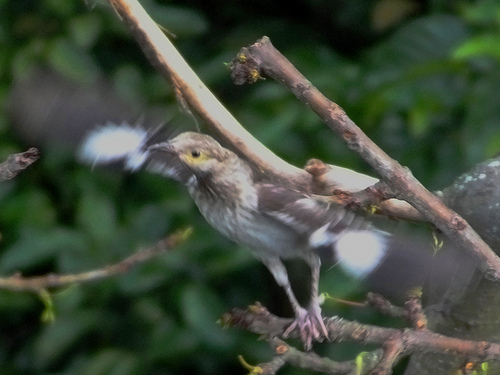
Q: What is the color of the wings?
A: White and black.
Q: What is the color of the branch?
A: Brown.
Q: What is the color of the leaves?
A: Green.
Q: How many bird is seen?
A: 1.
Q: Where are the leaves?
A: Behind the bird.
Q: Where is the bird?
A: In the branch.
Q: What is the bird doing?
A: Ready to fly.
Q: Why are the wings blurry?
A: They are in motion.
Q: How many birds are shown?
A: One.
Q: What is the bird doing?
A: Flying.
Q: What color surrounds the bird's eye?
A: Yellow.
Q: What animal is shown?
A: A bird.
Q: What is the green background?
A: Leaves.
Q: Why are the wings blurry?
A: The bird is flying.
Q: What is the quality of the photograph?
A: It is blurry.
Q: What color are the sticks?
A: Light brown.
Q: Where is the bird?
A: On a branch.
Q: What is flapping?
A: The bird's wing.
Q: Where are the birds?
A: In a tree.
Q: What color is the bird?
A: White and gray.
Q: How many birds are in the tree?
A: One.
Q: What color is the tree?
A: Brown.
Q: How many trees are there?
A: One.